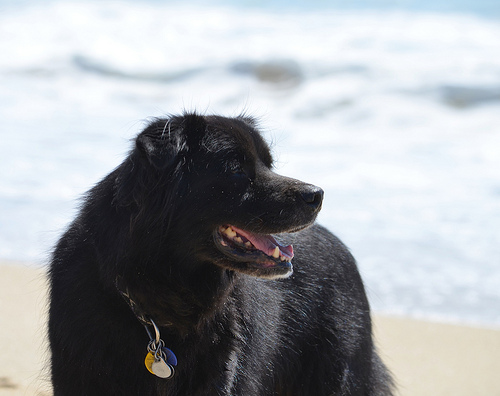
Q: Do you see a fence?
A: No, there are no fences.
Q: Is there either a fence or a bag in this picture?
A: No, there are no fences or bags.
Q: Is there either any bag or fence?
A: No, there are no fences or bags.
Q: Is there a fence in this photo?
A: No, there are no fences.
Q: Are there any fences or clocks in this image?
A: No, there are no fences or clocks.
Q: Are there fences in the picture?
A: No, there are no fences.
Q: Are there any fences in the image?
A: No, there are no fences.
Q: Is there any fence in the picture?
A: No, there are no fences.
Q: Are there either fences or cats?
A: No, there are no fences or cats.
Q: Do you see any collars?
A: Yes, there is a collar.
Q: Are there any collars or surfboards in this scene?
A: Yes, there is a collar.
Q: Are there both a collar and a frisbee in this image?
A: No, there is a collar but no frisbees.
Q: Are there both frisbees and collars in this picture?
A: No, there is a collar but no frisbees.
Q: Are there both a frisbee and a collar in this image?
A: No, there is a collar but no frisbees.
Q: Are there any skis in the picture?
A: No, there are no skis.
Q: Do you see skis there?
A: No, there are no skis.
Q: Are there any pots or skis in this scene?
A: No, there are no skis or pots.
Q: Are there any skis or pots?
A: No, there are no skis or pots.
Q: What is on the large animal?
A: The collar is on the dog.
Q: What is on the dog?
A: The collar is on the dog.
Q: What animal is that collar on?
A: The collar is on the dog.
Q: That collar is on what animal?
A: The collar is on the dog.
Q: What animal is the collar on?
A: The collar is on the dog.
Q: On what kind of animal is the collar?
A: The collar is on the dog.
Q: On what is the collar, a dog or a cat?
A: The collar is on a dog.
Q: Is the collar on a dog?
A: Yes, the collar is on a dog.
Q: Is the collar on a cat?
A: No, the collar is on a dog.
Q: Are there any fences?
A: No, there are no fences.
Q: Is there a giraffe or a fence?
A: No, there are no fences or giraffes.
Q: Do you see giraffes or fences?
A: No, there are no fences or giraffes.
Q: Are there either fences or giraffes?
A: No, there are no fences or giraffes.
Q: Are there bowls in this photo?
A: No, there are no bowls.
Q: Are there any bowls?
A: No, there are no bowls.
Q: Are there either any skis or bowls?
A: No, there are no bowls or skis.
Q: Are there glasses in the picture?
A: No, there are no glasses.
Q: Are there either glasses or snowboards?
A: No, there are no glasses or snowboards.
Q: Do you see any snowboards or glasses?
A: No, there are no glasses or snowboards.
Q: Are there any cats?
A: No, there are no cats.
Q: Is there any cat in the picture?
A: No, there are no cats.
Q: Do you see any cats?
A: No, there are no cats.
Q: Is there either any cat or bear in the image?
A: No, there are no cats or bears.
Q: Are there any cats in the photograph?
A: No, there are no cats.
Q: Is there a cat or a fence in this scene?
A: No, there are no cats or fences.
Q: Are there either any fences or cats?
A: No, there are no cats or fences.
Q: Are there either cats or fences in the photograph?
A: No, there are no cats or fences.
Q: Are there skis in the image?
A: No, there are no skis.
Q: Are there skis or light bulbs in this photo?
A: No, there are no skis or light bulbs.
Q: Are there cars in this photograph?
A: No, there are no cars.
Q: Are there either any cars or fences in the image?
A: No, there are no cars or fences.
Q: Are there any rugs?
A: No, there are no rugs.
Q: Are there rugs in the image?
A: No, there are no rugs.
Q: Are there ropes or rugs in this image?
A: No, there are no rugs or ropes.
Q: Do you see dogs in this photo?
A: Yes, there is a dog.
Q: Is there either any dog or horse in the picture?
A: Yes, there is a dog.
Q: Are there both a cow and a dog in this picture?
A: No, there is a dog but no cows.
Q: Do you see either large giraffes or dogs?
A: Yes, there is a large dog.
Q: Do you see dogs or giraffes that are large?
A: Yes, the dog is large.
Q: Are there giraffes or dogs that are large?
A: Yes, the dog is large.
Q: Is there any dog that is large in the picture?
A: Yes, there is a large dog.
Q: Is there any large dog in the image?
A: Yes, there is a large dog.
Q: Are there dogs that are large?
A: Yes, there is a dog that is large.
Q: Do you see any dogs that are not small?
A: Yes, there is a large dog.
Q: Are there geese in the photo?
A: No, there are no geese.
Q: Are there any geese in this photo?
A: No, there are no geese.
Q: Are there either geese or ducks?
A: No, there are no geese or ducks.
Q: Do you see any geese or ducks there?
A: No, there are no geese or ducks.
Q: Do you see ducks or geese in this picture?
A: No, there are no geese or ducks.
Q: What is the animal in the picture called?
A: The animal is a dog.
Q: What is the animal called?
A: The animal is a dog.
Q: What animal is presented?
A: The animal is a dog.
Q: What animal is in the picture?
A: The animal is a dog.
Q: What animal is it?
A: The animal is a dog.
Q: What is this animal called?
A: This is a dog.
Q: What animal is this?
A: This is a dog.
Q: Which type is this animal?
A: This is a dog.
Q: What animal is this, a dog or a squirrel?
A: This is a dog.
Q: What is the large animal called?
A: The animal is a dog.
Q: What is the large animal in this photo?
A: The animal is a dog.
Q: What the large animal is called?
A: The animal is a dog.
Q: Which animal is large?
A: The animal is a dog.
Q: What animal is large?
A: The animal is a dog.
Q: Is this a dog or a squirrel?
A: This is a dog.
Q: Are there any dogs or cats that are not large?
A: No, there is a dog but it is large.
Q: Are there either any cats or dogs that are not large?
A: No, there is a dog but it is large.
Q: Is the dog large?
A: Yes, the dog is large.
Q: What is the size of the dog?
A: The dog is large.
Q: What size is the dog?
A: The dog is large.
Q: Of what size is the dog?
A: The dog is large.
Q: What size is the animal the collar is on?
A: The dog is large.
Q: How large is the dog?
A: The dog is large.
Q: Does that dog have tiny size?
A: No, the dog is large.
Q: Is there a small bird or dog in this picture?
A: No, there is a dog but it is large.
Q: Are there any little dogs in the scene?
A: No, there is a dog but it is large.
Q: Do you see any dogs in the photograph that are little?
A: No, there is a dog but it is large.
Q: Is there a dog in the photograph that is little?
A: No, there is a dog but it is large.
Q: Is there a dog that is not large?
A: No, there is a dog but it is large.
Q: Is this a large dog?
A: Yes, this is a large dog.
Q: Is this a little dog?
A: No, this is a large dog.